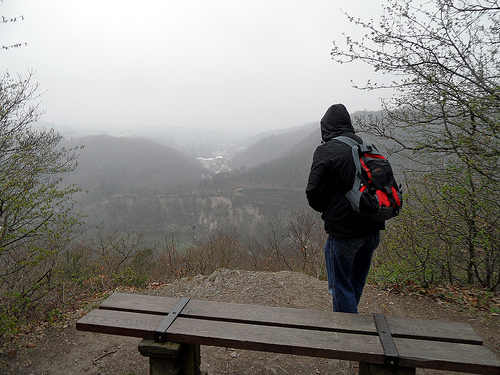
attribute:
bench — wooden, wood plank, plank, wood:
[75, 290, 495, 374]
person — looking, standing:
[305, 103, 401, 314]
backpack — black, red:
[347, 142, 402, 219]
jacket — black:
[304, 103, 403, 235]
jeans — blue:
[323, 229, 382, 313]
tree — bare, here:
[0, 11, 122, 374]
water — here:
[192, 154, 226, 163]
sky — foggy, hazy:
[0, 0, 491, 143]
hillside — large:
[199, 147, 325, 209]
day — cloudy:
[2, 0, 498, 374]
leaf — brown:
[429, 274, 495, 288]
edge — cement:
[213, 266, 299, 274]